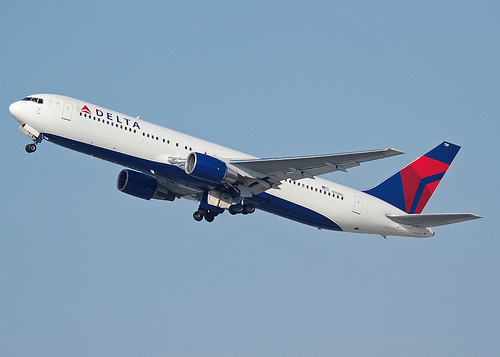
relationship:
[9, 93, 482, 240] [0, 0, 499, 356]
plane in sky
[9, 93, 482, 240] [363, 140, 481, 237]
plane has tail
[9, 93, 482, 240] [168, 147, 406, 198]
plane has wing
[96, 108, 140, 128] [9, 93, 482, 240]
word on side of plane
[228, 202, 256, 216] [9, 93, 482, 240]
back wheels are under plane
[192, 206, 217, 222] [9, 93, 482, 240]
back wheels are under plane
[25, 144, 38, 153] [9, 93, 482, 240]
front wheels are under plane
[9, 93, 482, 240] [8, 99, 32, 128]
plane has nose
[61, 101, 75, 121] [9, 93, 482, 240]
door on side of plane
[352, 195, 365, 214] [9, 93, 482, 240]
door on side of plane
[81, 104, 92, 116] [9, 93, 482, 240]
graphic logo on side of plane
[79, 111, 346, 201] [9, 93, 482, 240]
row of windows on side of plane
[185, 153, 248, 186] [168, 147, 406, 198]
engine below wing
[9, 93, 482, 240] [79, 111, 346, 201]
plane has row of windows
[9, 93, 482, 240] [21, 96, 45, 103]
plane has windshield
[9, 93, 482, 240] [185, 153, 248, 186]
plane has engine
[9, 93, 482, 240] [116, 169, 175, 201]
plane has engine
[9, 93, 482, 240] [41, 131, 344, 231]
plane has underbelly